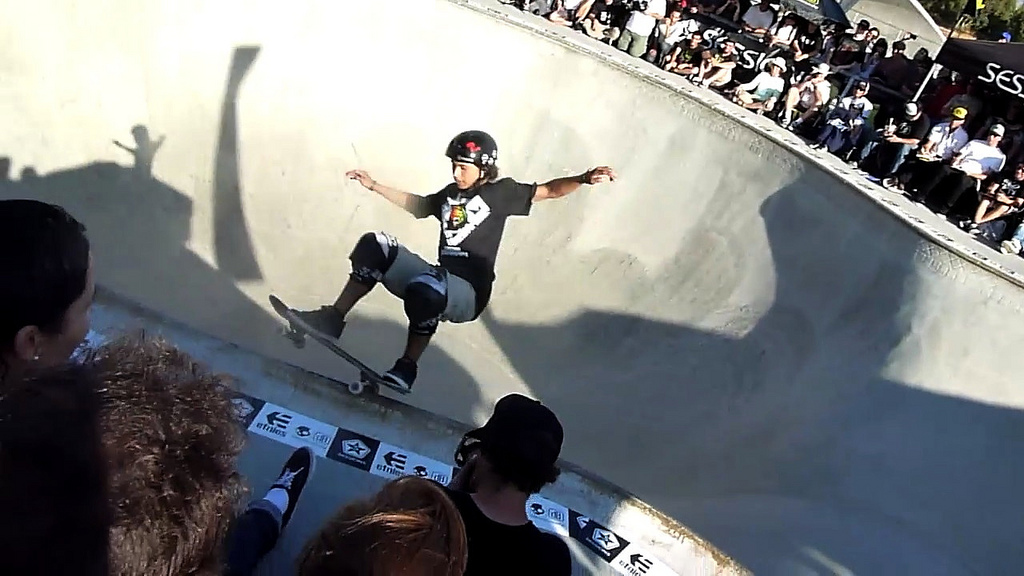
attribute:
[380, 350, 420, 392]
shoe — black, white , athletic 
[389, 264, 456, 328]
knee pad — black 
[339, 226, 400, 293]
knee pad — black 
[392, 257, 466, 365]
knee pad — black 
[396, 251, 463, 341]
knee pad — black 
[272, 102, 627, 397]
man — young , skateboarding